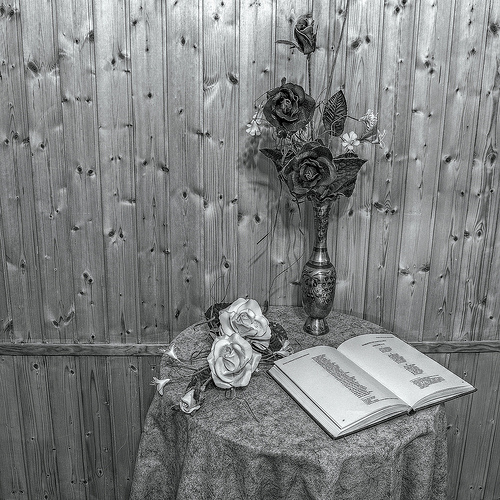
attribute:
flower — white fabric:
[241, 118, 265, 135]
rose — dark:
[260, 81, 317, 134]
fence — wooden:
[2, 2, 499, 499]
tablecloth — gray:
[118, 279, 473, 496]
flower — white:
[204, 332, 261, 392]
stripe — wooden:
[1, 327, 499, 379]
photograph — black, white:
[2, 1, 493, 498]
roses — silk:
[198, 285, 273, 406]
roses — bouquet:
[241, 21, 390, 242]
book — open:
[254, 340, 454, 411]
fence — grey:
[45, 107, 223, 315]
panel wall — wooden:
[4, 313, 499, 498]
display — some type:
[238, 26, 425, 333]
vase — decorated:
[291, 193, 340, 333]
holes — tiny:
[75, 163, 85, 175]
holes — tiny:
[85, 168, 95, 177]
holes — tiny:
[36, 142, 45, 149]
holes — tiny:
[143, 90, 153, 102]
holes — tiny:
[218, 138, 225, 147]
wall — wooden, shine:
[2, 0, 499, 497]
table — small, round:
[139, 298, 458, 484]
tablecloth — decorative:
[117, 297, 490, 496]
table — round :
[79, 243, 467, 495]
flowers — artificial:
[206, 331, 262, 391]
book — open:
[266, 323, 482, 442]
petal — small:
[170, 393, 199, 414]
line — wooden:
[4, 341, 170, 356]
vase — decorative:
[301, 204, 339, 334]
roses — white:
[199, 290, 277, 399]